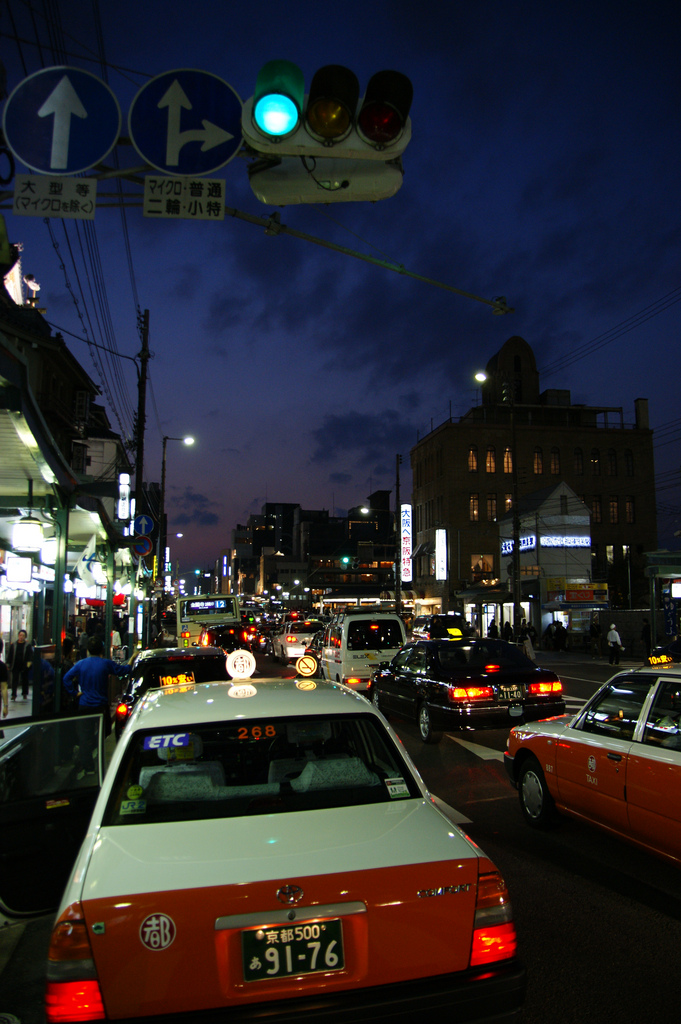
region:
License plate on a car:
[237, 917, 346, 983]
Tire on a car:
[514, 754, 553, 824]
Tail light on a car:
[466, 870, 524, 970]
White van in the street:
[315, 614, 410, 691]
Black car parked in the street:
[362, 633, 568, 740]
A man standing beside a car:
[58, 641, 135, 714]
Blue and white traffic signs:
[0, 53, 241, 181]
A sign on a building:
[396, 497, 412, 590]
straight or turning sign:
[128, 61, 254, 204]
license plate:
[219, 913, 395, 1002]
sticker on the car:
[116, 904, 197, 969]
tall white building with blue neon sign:
[479, 466, 636, 633]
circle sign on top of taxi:
[213, 637, 275, 695]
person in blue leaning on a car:
[64, 622, 146, 737]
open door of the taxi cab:
[1, 702, 164, 943]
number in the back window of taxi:
[228, 706, 297, 760]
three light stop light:
[244, 45, 486, 199]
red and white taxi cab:
[0, 679, 522, 1022]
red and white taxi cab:
[501, 663, 678, 863]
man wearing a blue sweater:
[55, 633, 132, 791]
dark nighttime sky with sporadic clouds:
[0, 1, 679, 597]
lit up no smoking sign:
[295, 653, 316, 676]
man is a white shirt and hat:
[602, 621, 628, 666]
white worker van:
[321, 610, 409, 692]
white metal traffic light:
[237, 56, 414, 162]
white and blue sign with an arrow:
[0, 64, 126, 174]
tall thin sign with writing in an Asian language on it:
[397, 502, 413, 583]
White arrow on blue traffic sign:
[35, 72, 89, 179]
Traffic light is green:
[250, 85, 304, 141]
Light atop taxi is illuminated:
[226, 648, 255, 679]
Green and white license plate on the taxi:
[233, 911, 341, 980]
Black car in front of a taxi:
[363, 625, 563, 736]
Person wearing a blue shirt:
[64, 636, 140, 779]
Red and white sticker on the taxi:
[136, 906, 177, 949]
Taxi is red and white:
[497, 653, 679, 869]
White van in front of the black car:
[319, 598, 406, 692]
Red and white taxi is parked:
[0, 646, 526, 1022]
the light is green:
[254, 92, 298, 137]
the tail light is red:
[472, 920, 513, 961]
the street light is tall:
[159, 434, 195, 562]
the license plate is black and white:
[238, 915, 344, 984]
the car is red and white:
[1, 647, 514, 1021]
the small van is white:
[319, 613, 406, 693]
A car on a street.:
[69, 680, 503, 995]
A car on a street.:
[508, 660, 675, 860]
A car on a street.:
[382, 639, 545, 746]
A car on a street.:
[409, 609, 488, 653]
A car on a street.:
[313, 612, 419, 692]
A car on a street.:
[273, 619, 341, 663]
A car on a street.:
[246, 624, 289, 655]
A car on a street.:
[197, 628, 266, 655]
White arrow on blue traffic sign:
[153, 72, 185, 156]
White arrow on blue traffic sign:
[34, 70, 91, 170]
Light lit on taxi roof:
[221, 644, 255, 678]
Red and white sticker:
[136, 906, 178, 947]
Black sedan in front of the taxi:
[364, 637, 562, 743]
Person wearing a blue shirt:
[61, 630, 138, 776]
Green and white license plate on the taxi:
[239, 913, 346, 982]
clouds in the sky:
[338, 307, 433, 366]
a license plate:
[233, 927, 353, 978]